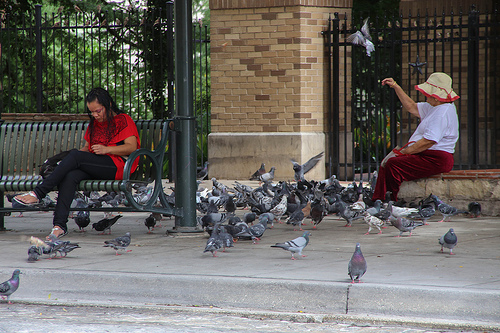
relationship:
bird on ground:
[1, 267, 24, 304] [0, 206, 498, 331]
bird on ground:
[88, 216, 124, 233] [5, 218, 155, 291]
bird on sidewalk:
[0, 268, 22, 303] [5, 206, 498, 328]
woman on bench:
[8, 86, 143, 241] [0, 123, 85, 188]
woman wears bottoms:
[370, 70, 461, 213] [365, 144, 460, 205]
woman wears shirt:
[364, 67, 461, 219] [410, 98, 460, 155]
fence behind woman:
[40, 41, 222, 81] [6, 79, 153, 245]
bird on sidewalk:
[346, 242, 366, 284] [1, 178, 498, 325]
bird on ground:
[81, 216, 126, 234] [401, 261, 498, 288]